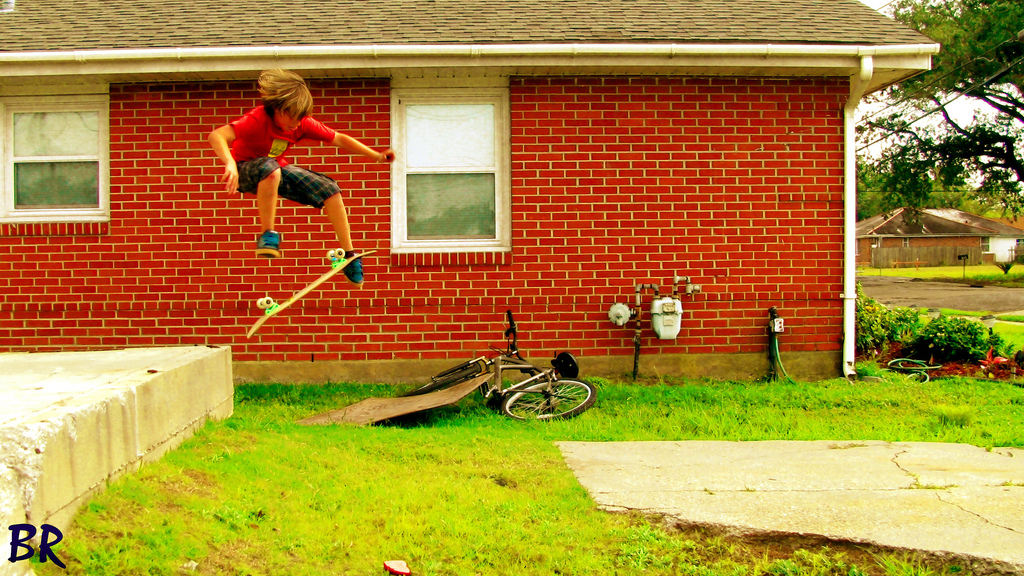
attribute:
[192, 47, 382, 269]
boy — young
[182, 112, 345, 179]
shirt — red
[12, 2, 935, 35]
shingle — black, roof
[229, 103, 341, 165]
t-shirt — red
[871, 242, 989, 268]
fence — wooden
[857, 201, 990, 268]
house — large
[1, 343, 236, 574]
concrete slab — slightly damaged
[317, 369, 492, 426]
wood piece — slightly damaged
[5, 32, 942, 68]
drain pipe — horizontal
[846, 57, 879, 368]
drain pipe — vertical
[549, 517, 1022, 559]
edge — broken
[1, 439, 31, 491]
edge — chipped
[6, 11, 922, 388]
building — side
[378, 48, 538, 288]
frame — white